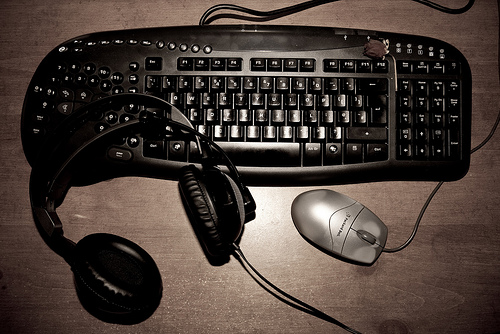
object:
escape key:
[144, 55, 163, 71]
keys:
[334, 92, 350, 110]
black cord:
[197, 1, 477, 28]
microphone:
[136, 109, 170, 128]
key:
[238, 108, 249, 123]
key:
[219, 107, 236, 123]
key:
[203, 107, 219, 122]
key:
[214, 93, 231, 105]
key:
[201, 91, 215, 106]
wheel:
[360, 233, 375, 243]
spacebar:
[206, 140, 300, 167]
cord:
[380, 116, 499, 255]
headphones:
[26, 91, 256, 326]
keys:
[185, 108, 204, 121]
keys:
[225, 124, 242, 140]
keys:
[243, 123, 262, 140]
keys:
[318, 93, 334, 108]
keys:
[298, 92, 316, 104]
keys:
[360, 139, 388, 165]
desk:
[0, 0, 499, 333]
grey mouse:
[290, 187, 389, 267]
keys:
[335, 109, 352, 126]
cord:
[228, 243, 355, 333]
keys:
[164, 92, 181, 107]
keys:
[443, 127, 465, 160]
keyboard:
[19, 22, 474, 187]